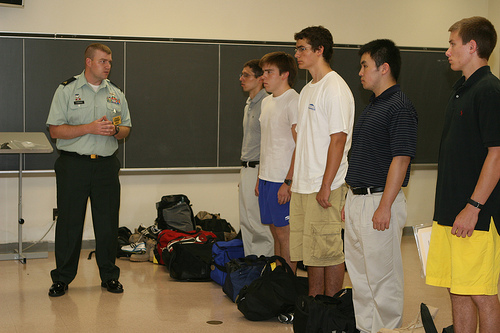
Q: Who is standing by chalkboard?
A: Military officer.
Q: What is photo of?
A: Five young men and officer.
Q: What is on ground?
A: Bags.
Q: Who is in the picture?
A: Boys and an officer.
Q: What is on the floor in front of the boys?
A: Luggage packs and bags.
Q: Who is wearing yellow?
A: The far right boy.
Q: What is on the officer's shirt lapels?
A: Awards.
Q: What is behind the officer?
A: Chalkboard.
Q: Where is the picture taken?
A: A classroom.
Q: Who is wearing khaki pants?
A: The Asian boy.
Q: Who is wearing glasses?
A: The boy in khaki shorts and white shirt.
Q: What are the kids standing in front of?
A: An officer.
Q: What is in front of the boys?
A: Duffel bags.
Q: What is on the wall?
A: A chalkboard.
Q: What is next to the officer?
A: A table.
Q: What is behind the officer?
A: A blackboard.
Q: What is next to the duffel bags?
A: The kids.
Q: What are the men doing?
A: Standing.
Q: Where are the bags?
A: On the ground.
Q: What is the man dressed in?
A: A uniform.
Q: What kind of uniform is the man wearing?
A: A military uniform.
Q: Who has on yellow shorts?
A: Man.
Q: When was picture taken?
A: Daytime.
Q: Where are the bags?
A: Floor.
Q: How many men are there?
A: Six.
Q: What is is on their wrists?
A: Watches.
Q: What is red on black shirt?
A: Emblem.